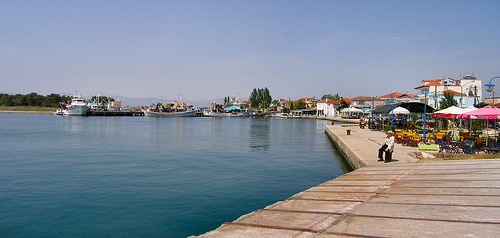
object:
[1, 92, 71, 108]
tree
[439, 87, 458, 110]
tree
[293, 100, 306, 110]
tree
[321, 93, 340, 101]
tree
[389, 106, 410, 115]
umbrella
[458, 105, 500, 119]
umbrella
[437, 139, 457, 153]
chair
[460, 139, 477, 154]
chair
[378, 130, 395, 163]
person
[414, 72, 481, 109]
building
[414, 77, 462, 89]
roof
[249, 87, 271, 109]
leaves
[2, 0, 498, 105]
sky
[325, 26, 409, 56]
clouds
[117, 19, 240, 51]
clouds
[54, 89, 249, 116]
boats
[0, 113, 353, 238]
water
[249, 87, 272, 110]
clump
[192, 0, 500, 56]
clouds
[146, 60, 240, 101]
clouds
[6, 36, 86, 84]
clouds